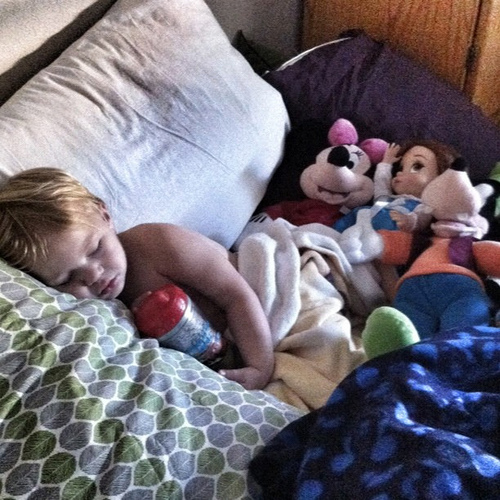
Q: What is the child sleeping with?
A: A bottle.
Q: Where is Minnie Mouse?
A: On the bed.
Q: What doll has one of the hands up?
A: The middle doll.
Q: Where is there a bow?
A: On minnie mouse's head.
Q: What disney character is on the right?
A: Goofy.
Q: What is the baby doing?
A: Sleeping.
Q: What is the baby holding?
A: A plastic cup with a red lid on it.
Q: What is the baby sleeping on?
A: The baby is sleeping on a bed.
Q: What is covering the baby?
A: A blanket.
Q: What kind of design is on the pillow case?
A: Polka dots.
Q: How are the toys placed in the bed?
A: Toys are placed beside one another.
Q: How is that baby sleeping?
A: Baby is sleeping with holding a cup.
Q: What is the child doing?
A: Sleeping.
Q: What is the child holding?
A: Cup.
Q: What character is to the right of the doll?
A: Goofy.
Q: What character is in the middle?
A: Belle.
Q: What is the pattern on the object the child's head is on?
A: Leaves.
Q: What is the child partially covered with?
A: Blanket.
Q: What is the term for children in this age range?
A: Toddler.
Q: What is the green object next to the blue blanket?
A: Goofy's foot.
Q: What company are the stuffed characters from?
A: Disney.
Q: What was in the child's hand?
A: A cup.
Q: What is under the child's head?
A: A pillow.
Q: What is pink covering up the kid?
A: A blanket.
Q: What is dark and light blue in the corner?
A: A blanket.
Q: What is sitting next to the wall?
A: A pillow.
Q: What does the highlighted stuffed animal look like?
A: Goofy.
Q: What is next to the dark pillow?
A: A cabinet.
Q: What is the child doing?
A: Sleeping.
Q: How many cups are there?
A: One.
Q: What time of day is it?
A: Daytime.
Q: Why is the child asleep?
A: Naptime.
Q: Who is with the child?
A: No one.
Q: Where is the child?
A: In bed.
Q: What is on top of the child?
A: Blanket.